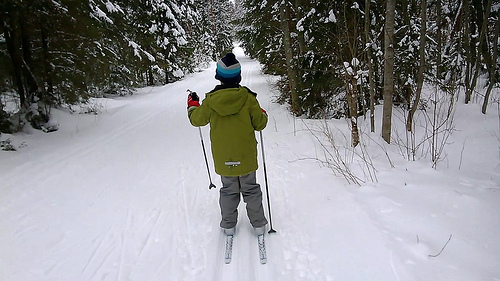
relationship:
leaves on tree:
[360, 60, 370, 79] [333, 1, 368, 145]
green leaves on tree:
[86, 45, 96, 54] [0, 0, 52, 132]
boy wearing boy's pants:
[184, 53, 276, 237] [218, 173, 268, 228]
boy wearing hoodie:
[184, 53, 276, 237] [187, 84, 268, 176]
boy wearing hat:
[184, 53, 276, 237] [188, 47, 280, 159]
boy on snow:
[184, 53, 276, 237] [0, 69, 497, 279]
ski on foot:
[223, 232, 233, 265] [219, 222, 236, 233]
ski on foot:
[251, 215, 271, 269] [251, 220, 266, 235]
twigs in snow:
[304, 119, 432, 205] [297, 172, 444, 271]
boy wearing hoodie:
[164, 39, 359, 276] [187, 85, 268, 177]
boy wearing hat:
[184, 53, 276, 237] [213, 53, 242, 83]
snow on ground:
[97, 126, 172, 199] [1, 42, 498, 279]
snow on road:
[37, 174, 188, 279] [3, 45, 311, 279]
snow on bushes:
[27, 100, 111, 169] [1, 9, 106, 161]